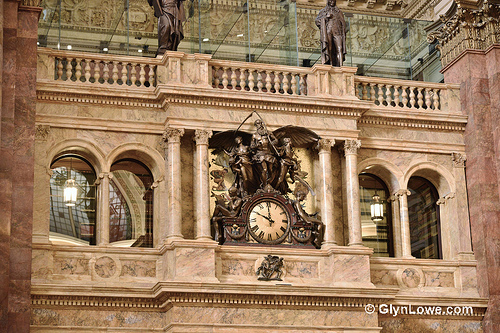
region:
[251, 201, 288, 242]
ivory clock on building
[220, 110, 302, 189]
bronze statue on building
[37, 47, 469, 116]
stone barrier fence on building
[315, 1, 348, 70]
bronze statue on railing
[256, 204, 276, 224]
black hands on clock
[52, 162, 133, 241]
glass window on building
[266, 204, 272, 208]
roman numeral number twelve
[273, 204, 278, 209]
roman numeral number one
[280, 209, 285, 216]
roman numeral number two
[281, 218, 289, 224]
roman numeral number three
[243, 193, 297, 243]
large round clock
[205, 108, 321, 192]
statue of angel over clock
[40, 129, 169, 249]
arched windows at sides of clock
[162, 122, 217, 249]
decorative columns beside clock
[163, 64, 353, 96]
railing above clock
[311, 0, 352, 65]
stature above clock area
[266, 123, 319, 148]
angel's wing of sculpture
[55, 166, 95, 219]
lamp shining through window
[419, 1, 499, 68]
ornate details at top of columns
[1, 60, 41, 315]
stone columns at sides of clock feature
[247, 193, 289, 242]
The clock on the structure.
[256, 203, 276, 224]
The hands of the clock.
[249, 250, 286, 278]
The small statue beneath the clock.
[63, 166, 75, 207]
The hanging lamp on the left.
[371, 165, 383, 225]
The hanging lamp on the right.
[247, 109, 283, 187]
The man in the center of the statue above the clock.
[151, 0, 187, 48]
The statue on the left on the top of the structure.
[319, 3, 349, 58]
The statue on the right on the top of the structure.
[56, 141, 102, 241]
The left archway on the left.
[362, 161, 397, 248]
The left archway on the right.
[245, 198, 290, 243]
The face of a clock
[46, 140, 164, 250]
Two arches with windows in them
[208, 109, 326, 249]
A statue with a clock on the front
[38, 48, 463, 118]
A section of ornate railing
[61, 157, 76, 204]
Lighting fixture hanging from the ceiling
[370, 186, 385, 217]
Light fixture hanging from the ceiling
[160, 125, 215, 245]
Two columns with ornate moldings.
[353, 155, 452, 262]
Two arches with a mirror inside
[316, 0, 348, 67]
A detailed statue of a man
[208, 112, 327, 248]
A detailed brass status with a clock on it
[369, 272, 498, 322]
words are written inwhite color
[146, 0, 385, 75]
two sculpture on the balcony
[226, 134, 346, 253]
clock is on the wall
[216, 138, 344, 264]
there are peopl sculpture on the clock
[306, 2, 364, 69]
sculpture is black in color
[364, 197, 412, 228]
the light globe is white in color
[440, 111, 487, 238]
wall ois brown in color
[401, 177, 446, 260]
Window of a building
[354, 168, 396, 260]
Window of a building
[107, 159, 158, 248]
Window of a building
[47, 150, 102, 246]
Window of a building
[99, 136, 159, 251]
ancient window arch way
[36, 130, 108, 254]
ancient window arch way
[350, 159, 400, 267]
ancient window arch way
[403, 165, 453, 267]
ancient window arch way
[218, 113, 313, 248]
bronze clock center piece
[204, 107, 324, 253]
old clock center piece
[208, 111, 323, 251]
ancient old clock center piece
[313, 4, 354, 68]
statue presiding over the clock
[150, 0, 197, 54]
statue presiding over the clock